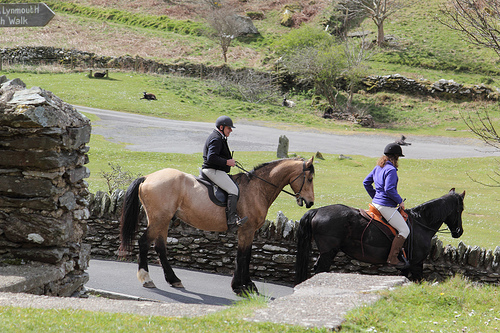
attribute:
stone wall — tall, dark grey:
[7, 64, 119, 306]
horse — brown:
[108, 147, 324, 307]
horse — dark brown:
[281, 176, 484, 302]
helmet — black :
[212, 113, 237, 136]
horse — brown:
[143, 158, 319, 276]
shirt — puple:
[368, 154, 400, 205]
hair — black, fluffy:
[117, 175, 145, 266]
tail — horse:
[117, 172, 144, 259]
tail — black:
[294, 209, 316, 282]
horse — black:
[294, 183, 467, 293]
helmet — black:
[217, 114, 242, 131]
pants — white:
[371, 197, 410, 239]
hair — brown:
[376, 156, 396, 167]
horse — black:
[289, 182, 474, 287]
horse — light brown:
[117, 159, 317, 299]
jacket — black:
[202, 125, 234, 173]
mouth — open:
[295, 194, 315, 208]